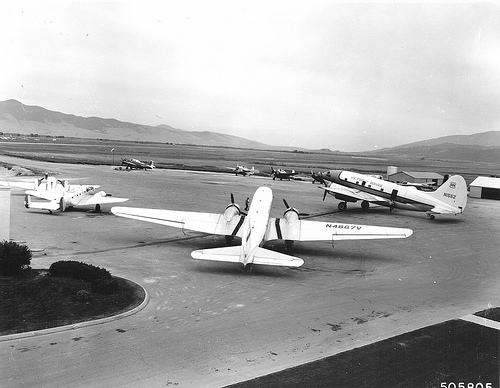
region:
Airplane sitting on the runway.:
[105, 178, 415, 286]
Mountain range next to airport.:
[0, 93, 420, 288]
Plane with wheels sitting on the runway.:
[304, 152, 476, 220]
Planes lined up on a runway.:
[1, 145, 496, 340]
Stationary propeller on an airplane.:
[274, 192, 318, 233]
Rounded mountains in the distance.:
[362, 113, 496, 151]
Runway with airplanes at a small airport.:
[0, 142, 498, 314]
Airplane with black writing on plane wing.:
[107, 188, 408, 289]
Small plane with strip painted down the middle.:
[304, 161, 479, 223]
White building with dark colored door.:
[465, 162, 497, 209]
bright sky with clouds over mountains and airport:
[2, 7, 496, 179]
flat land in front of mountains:
[5, 95, 497, 174]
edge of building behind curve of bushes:
[1, 174, 151, 344]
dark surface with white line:
[216, 303, 499, 385]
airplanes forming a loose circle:
[6, 145, 469, 272]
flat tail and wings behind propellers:
[111, 181, 411, 283]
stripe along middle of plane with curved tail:
[306, 154, 478, 217]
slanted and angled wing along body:
[35, 178, 127, 223]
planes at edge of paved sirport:
[116, 147, 314, 186]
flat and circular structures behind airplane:
[380, 160, 499, 201]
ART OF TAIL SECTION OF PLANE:
[186, 243, 310, 275]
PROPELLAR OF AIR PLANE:
[281, 195, 310, 216]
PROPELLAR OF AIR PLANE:
[221, 190, 249, 212]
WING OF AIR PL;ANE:
[303, 215, 423, 245]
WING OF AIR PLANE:
[108, 203, 210, 235]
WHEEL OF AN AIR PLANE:
[331, 199, 358, 214]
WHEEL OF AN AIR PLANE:
[356, 198, 366, 210]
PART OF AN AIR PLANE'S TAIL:
[436, 171, 471, 205]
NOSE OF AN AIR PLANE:
[249, 185, 282, 198]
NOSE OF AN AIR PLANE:
[308, 165, 327, 180]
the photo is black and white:
[0, 0, 497, 385]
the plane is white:
[108, 178, 419, 283]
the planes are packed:
[6, 170, 470, 270]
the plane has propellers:
[225, 194, 307, 220]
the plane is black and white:
[319, 170, 465, 215]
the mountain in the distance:
[1, 96, 498, 157]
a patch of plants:
[1, 236, 149, 338]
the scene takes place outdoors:
[0, 3, 495, 383]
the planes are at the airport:
[0, 155, 499, 385]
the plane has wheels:
[340, 197, 372, 212]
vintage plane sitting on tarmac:
[134, 198, 408, 274]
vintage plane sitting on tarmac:
[330, 159, 469, 221]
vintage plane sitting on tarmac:
[305, 165, 321, 184]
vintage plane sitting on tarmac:
[267, 162, 292, 186]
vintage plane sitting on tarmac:
[232, 158, 264, 178]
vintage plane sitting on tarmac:
[125, 153, 155, 172]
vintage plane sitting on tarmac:
[28, 166, 97, 217]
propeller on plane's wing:
[213, 189, 243, 239]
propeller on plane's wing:
[278, 201, 301, 243]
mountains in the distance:
[25, 101, 492, 169]